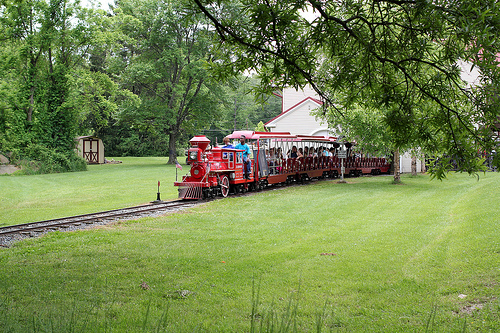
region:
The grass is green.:
[227, 215, 347, 312]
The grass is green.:
[282, 182, 353, 302]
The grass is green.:
[321, 245, 371, 325]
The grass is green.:
[320, 285, 365, 329]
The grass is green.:
[330, 274, 390, 329]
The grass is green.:
[305, 237, 383, 298]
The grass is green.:
[318, 308, 350, 330]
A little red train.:
[163, 105, 409, 200]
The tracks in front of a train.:
[5, 192, 191, 247]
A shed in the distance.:
[66, 130, 111, 165]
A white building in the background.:
[245, 77, 345, 129]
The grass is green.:
[262, 202, 468, 267]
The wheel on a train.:
[215, 176, 230, 196]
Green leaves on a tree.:
[330, 2, 491, 132]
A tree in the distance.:
[100, 0, 220, 160]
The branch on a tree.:
[195, 0, 355, 130]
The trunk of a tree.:
[165, 126, 180, 162]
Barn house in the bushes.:
[80, 134, 109, 171]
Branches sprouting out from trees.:
[268, 45, 318, 80]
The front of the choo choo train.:
[173, 131, 221, 208]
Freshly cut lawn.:
[207, 204, 342, 269]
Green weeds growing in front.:
[238, 282, 313, 330]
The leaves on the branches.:
[358, 97, 433, 152]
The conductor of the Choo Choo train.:
[226, 126, 261, 184]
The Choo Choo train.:
[169, 120, 401, 204]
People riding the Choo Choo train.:
[266, 144, 342, 164]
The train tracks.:
[15, 203, 119, 235]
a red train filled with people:
[172, 130, 394, 200]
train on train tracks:
[2, 129, 394, 238]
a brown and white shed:
[74, 132, 107, 164]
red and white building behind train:
[265, 85, 343, 133]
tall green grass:
[1, 275, 498, 332]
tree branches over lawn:
[193, 2, 498, 180]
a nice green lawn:
[1, 152, 498, 331]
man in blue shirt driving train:
[234, 135, 249, 158]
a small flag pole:
[172, 162, 181, 182]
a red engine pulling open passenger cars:
[174, 119, 393, 202]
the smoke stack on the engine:
[181, 131, 208, 166]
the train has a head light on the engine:
[184, 149, 201, 164]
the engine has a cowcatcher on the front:
[172, 181, 211, 201]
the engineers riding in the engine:
[220, 133, 253, 183]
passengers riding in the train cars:
[261, 140, 355, 172]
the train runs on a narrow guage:
[2, 190, 207, 245]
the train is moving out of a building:
[261, 68, 426, 178]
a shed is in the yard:
[71, 131, 112, 166]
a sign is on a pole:
[336, 146, 348, 187]